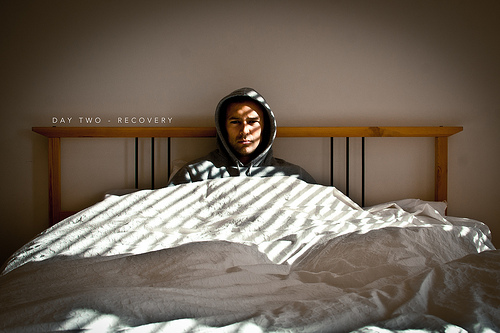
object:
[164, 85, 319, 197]
man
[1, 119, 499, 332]
bed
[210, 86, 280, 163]
hood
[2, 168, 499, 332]
bedding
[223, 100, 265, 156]
face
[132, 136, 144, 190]
pole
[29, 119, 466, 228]
headboard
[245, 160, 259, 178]
string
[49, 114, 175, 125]
words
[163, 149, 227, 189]
shoulder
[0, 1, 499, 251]
wall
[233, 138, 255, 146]
lips